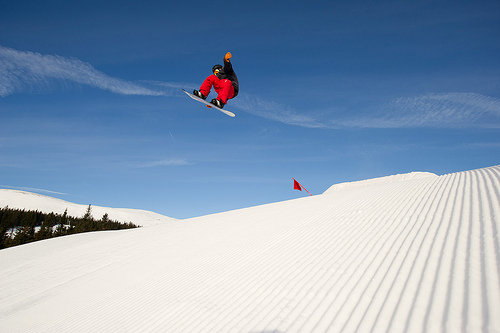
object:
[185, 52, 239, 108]
man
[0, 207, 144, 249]
trees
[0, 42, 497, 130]
cloud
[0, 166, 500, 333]
snow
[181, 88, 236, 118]
snowboard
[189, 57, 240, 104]
snowsuit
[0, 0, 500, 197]
sky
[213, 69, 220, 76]
goggles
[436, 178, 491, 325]
lines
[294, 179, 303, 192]
flag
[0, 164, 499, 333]
slope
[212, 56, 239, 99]
jacket